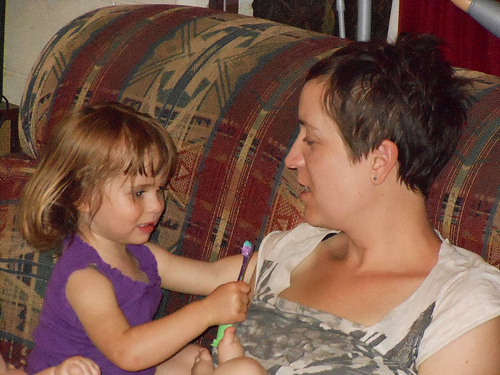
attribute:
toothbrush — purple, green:
[204, 237, 262, 350]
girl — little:
[15, 97, 271, 372]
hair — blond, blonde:
[14, 93, 182, 262]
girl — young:
[18, 100, 249, 374]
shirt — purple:
[25, 234, 155, 372]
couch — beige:
[2, 1, 496, 374]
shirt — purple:
[20, 233, 167, 372]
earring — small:
[366, 177, 400, 202]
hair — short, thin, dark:
[312, 36, 462, 194]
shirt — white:
[216, 222, 498, 372]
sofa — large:
[147, 30, 259, 150]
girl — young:
[33, 95, 226, 373]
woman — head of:
[235, 19, 401, 372]